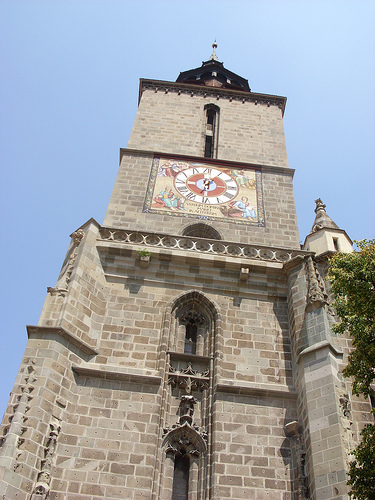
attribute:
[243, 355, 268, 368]
stone — brown and gray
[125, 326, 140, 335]
brick — brown and gray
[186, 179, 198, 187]
line — small white 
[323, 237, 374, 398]
tree — green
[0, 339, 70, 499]
brick work — ornate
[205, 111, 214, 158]
church wondow — tall, slender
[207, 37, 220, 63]
tip — pointy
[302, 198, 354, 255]
tower — tall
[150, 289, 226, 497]
archway — two story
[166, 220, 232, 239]
arch — small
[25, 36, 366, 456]
church tower — large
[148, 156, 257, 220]
figures — colorful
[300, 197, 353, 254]
cupola — stucco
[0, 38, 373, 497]
tower — large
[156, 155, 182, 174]
people — four 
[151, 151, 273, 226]
clock —  edge 